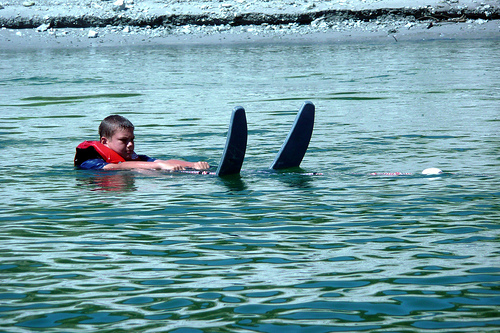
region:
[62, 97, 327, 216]
Person wearing skis floating in the water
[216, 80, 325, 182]
Pair of blue water skis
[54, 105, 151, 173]
Person wearing red life vest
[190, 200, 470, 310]
Blue water with small ripples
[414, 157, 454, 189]
White bobber attached to ski rope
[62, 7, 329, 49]
Rocky beach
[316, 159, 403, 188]
Ski rope laying on top of the water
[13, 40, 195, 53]
Stretch of sand on the shore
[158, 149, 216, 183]
Hands holding onto bar for ski rope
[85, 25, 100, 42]
Large rock by the shore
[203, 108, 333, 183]
Water skis sticking out of the water.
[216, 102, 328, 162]
The water skis are blue.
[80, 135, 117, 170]
The boy is wearing a vest.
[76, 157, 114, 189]
The boy is wearing a blue shirt.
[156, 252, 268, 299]
The water is blue.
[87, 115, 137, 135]
The boy has short hair.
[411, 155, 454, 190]
A white object in the water.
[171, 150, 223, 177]
The boy is holding a rope.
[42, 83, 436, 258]
The boy is in the water.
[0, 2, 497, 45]
Where the water and the beach connect.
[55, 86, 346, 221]
water skier mostly submerged in water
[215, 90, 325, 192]
tips of skis pointed upward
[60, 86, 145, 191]
red life jacket curled over shoulder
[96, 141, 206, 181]
arms extended and hands curled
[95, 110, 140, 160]
child with concentrated look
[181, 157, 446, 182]
rope and white object floating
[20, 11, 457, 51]
light-colored rocks along the shore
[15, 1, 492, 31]
ledge behind the rocks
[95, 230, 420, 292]
blues and greens swirling on water surface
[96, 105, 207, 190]
skin on face and arms turning deep pink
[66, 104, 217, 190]
Boy in the water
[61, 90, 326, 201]
Boy wears aquatic skis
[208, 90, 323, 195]
Aquatic skis are blue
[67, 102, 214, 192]
Boy has red vest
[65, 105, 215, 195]
Boy wears blue t-shirt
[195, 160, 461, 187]
Rope in the water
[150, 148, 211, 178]
Hans grab aquatic skis handle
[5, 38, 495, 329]
Water is calm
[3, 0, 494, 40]
Small stones in shore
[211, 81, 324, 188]
Aquatic skis point up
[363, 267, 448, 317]
part of a water surface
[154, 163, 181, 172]
part of the right hand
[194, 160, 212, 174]
part of the left hand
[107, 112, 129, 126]
hair of a boy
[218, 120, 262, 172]
edge of a board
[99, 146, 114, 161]
part of a floater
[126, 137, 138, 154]
nose of the boy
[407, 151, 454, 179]
part of a bate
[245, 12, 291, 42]
edge of a shore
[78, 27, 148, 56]
part of some stones